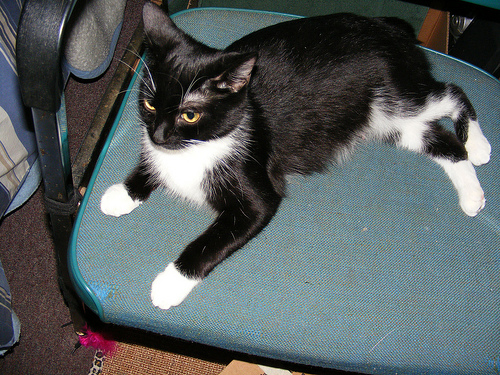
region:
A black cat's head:
[126, 18, 265, 161]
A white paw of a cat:
[143, 255, 215, 312]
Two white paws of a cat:
[83, 174, 212, 319]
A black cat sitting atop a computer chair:
[83, 10, 496, 312]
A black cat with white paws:
[80, 16, 495, 314]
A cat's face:
[128, 78, 216, 159]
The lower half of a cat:
[304, 0, 496, 246]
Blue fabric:
[268, 223, 499, 370]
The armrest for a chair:
[18, 0, 120, 257]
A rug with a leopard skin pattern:
[55, 323, 133, 374]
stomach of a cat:
[296, 85, 349, 122]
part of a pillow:
[337, 283, 394, 332]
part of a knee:
[217, 198, 281, 228]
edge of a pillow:
[178, 303, 229, 352]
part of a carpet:
[26, 297, 85, 356]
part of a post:
[50, 200, 62, 245]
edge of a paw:
[137, 280, 184, 315]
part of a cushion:
[358, 247, 401, 296]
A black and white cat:
[97, 3, 491, 278]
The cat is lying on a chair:
[98, 15, 478, 302]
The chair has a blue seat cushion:
[38, 5, 492, 344]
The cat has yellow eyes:
[122, 27, 243, 179]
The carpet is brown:
[6, 12, 154, 366]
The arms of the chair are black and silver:
[18, 5, 153, 300]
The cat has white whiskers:
[124, 36, 214, 169]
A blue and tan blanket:
[3, 5, 103, 217]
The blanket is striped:
[3, 9, 90, 209]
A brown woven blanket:
[92, 333, 282, 367]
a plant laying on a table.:
[97, 5, 498, 318]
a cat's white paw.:
[149, 261, 211, 316]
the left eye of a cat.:
[176, 107, 218, 129]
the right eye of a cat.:
[131, 94, 166, 129]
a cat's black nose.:
[144, 122, 172, 139]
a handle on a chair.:
[16, 0, 133, 228]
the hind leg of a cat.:
[384, 81, 498, 170]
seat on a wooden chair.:
[66, 54, 493, 371]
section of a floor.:
[79, 339, 190, 372]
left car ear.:
[209, 53, 265, 95]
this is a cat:
[116, 9, 432, 264]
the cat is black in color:
[106, 21, 426, 257]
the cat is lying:
[84, 14, 416, 291]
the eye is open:
[179, 105, 207, 125]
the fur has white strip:
[171, 146, 222, 178]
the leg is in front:
[143, 235, 253, 293]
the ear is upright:
[212, 50, 262, 97]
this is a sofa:
[306, 212, 468, 339]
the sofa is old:
[325, 244, 461, 373]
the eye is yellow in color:
[180, 106, 205, 123]